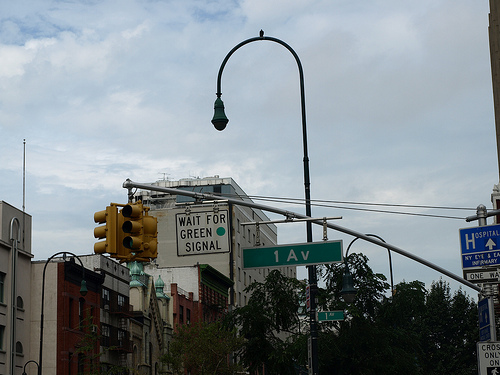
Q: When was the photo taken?
A: During daylight hours.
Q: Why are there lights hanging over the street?
A: Traffic control.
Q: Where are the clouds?
A: In the sky.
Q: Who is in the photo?
A: No person.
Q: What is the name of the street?
A: First Avenue.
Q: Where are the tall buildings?
A: Across the street.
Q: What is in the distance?
A: Trees.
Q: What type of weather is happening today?
A: Cloudy weather.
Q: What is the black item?
A: A street light.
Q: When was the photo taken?
A: During the day.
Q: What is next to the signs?
A: A traffic light.